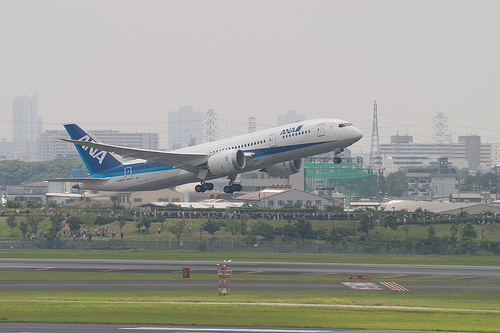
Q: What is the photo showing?
A: It is showing an airport.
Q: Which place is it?
A: It is an airport.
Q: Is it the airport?
A: Yes, it is the airport.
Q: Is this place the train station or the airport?
A: It is the airport.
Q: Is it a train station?
A: No, it is an airport.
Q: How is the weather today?
A: It is overcast.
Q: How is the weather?
A: It is overcast.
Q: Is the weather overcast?
A: Yes, it is overcast.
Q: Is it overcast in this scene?
A: Yes, it is overcast.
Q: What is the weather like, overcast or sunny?
A: It is overcast.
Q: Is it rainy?
A: No, it is overcast.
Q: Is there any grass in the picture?
A: Yes, there is grass.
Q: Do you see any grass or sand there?
A: Yes, there is grass.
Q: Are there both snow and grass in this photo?
A: No, there is grass but no snow.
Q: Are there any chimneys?
A: No, there are no chimneys.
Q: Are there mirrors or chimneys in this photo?
A: No, there are no chimneys or mirrors.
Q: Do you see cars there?
A: No, there are no cars.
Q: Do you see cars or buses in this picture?
A: No, there are no cars or buses.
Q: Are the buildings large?
A: Yes, the buildings are large.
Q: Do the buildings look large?
A: Yes, the buildings are large.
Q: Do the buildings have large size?
A: Yes, the buildings are large.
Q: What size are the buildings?
A: The buildings are large.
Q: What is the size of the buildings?
A: The buildings are large.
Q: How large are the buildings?
A: The buildings are large.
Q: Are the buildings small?
A: No, the buildings are large.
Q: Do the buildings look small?
A: No, the buildings are large.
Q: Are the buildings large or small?
A: The buildings are large.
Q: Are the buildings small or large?
A: The buildings are large.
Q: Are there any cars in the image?
A: No, there are no cars.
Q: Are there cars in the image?
A: No, there are no cars.